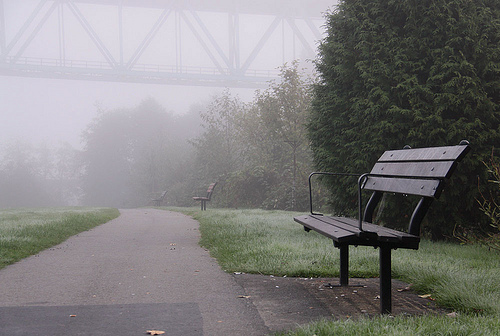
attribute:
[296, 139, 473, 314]
bench — black, wooden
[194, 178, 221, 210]
bench — black, wooden, wood, bolted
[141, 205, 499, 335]
grass — green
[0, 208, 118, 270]
grass — green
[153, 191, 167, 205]
bench — black, brown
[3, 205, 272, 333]
road — paved, tarmac, asphalt, curvy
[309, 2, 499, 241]
bush — green, large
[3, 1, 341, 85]
bridge — raised, elevated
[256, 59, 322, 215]
tree — green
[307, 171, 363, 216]
armrest — metal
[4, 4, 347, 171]
sky — hazy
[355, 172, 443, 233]
armrest — metal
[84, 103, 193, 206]
foliage — blurry